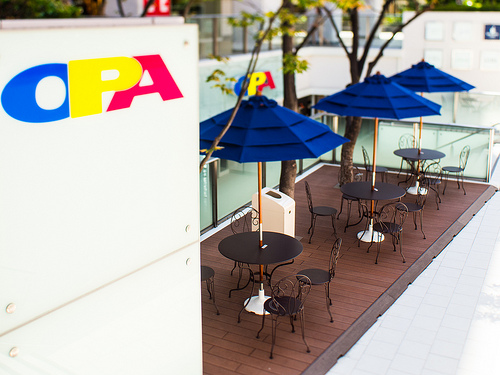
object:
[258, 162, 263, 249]
pole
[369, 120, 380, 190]
pole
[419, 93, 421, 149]
pole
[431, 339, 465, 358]
tile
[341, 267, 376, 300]
red wood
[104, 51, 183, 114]
letter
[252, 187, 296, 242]
white metal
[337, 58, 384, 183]
tree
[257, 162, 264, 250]
parasol handle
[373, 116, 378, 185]
parasol handle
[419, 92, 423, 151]
parasol handle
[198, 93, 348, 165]
parasol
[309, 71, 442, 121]
parasol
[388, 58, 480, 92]
parasol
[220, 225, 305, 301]
deck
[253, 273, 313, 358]
chair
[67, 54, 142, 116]
letter "p"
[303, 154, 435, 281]
patio table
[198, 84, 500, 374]
patio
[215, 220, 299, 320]
table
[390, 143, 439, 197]
table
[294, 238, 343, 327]
chair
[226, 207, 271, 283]
chair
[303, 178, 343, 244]
chair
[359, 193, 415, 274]
chair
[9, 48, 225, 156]
logo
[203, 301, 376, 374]
floor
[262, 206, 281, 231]
white